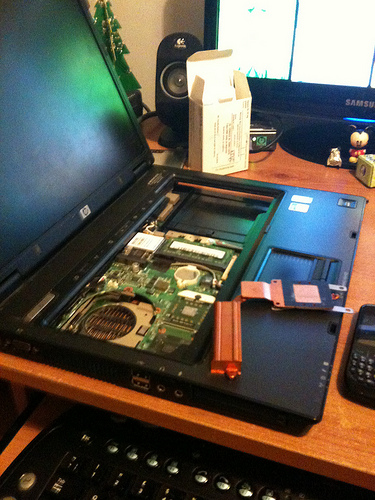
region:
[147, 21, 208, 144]
this is a speaker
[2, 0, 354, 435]
a broken laptop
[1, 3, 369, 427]
a broken notebook computer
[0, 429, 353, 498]
this is a black keyboard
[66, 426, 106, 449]
the Escape key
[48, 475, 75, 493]
this is the tab key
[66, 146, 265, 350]
the keyboard is missing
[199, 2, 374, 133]
a Samsung computer monitor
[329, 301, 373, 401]
this is a cell phone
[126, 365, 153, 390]
these are USB ports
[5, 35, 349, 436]
A laptop computer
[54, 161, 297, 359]
The keyboard has been taken off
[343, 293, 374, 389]
A cell phone on the desk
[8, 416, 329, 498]
A keyboard for a desktop computer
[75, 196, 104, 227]
Computer made by HP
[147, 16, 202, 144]
A computer speaker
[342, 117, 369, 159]
A small Mickey Mouse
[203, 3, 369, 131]
A flat screen TV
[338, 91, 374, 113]
TV is made by Samsung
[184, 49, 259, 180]
An open white box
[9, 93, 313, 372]
a laptop being repaired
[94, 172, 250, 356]
the keyboard is missing from this laptop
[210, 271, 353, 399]
an orange device on the laptop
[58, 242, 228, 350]
electronic parts inside of the computer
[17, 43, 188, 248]
a black computer screen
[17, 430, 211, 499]
a black keyboard beneath the laptop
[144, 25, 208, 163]
a speaker in the background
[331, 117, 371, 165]
a toy on the desk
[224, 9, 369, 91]
a window in the room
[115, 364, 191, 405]
jacks on the laptop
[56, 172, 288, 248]
computer being dismantledcomputer being dismantled at deskcomputer being dismantled at desk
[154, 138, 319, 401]
computer being dismantledcomputer being dismantled at deskcomputer being dismantled at desk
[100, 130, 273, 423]
computer being dismantledcomputer being dismantled at deskcomputer being dismantled at desk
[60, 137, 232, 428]
computer being dismantledcomputer being dismantled at desk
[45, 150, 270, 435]
computer being dismantledcomputer being dismantled at desk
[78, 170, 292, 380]
computer being dismantled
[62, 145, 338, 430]
computer being dismantledcomputer being dismantled at desk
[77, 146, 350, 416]
computer being dismantled at desk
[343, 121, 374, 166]
little mickey mouse figurine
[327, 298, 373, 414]
small black plastic cell phone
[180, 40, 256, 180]
small white card board box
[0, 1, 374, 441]
black plastic hewlett packard lap top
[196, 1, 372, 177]
illuminated samsung computer monitor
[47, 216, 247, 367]
exposed computer circuitry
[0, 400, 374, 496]
black and silver plastic computer key board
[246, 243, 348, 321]
worn black mouse touch pad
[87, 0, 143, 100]
small plastic christmas tree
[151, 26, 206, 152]
black and silver logitech computer speakers